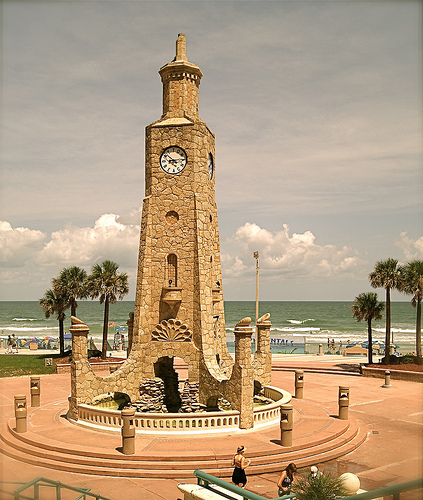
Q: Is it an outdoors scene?
A: Yes, it is outdoors.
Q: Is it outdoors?
A: Yes, it is outdoors.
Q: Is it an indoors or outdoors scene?
A: It is outdoors.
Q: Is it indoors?
A: No, it is outdoors.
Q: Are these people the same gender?
A: Yes, all the people are female.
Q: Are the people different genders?
A: No, all the people are female.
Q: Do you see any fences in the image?
A: No, there are no fences.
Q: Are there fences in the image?
A: No, there are no fences.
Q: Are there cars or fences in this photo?
A: No, there are no fences or cars.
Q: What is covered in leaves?
A: The palm is covered in leaves.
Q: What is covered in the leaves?
A: The palm is covered in leaves.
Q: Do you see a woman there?
A: Yes, there is a woman.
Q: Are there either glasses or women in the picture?
A: Yes, there is a woman.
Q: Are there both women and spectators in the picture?
A: No, there is a woman but no spectators.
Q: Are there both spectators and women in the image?
A: No, there is a woman but no spectators.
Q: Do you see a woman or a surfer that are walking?
A: Yes, the woman is walking.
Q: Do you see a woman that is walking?
A: Yes, there is a woman that is walking.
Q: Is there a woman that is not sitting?
A: Yes, there is a woman that is walking.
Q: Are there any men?
A: No, there are no men.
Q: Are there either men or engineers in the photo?
A: No, there are no men or engineers.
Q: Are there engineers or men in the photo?
A: No, there are no men or engineers.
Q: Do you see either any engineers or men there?
A: No, there are no men or engineers.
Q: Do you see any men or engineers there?
A: No, there are no men or engineers.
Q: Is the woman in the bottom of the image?
A: Yes, the woman is in the bottom of the image.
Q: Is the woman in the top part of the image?
A: No, the woman is in the bottom of the image.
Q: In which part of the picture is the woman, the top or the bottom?
A: The woman is in the bottom of the image.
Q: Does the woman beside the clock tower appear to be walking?
A: Yes, the woman is walking.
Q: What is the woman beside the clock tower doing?
A: The woman is walking.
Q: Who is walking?
A: The woman is walking.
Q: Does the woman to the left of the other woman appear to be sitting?
A: No, the woman is walking.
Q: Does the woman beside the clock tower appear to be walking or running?
A: The woman is walking.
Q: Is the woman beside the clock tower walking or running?
A: The woman is walking.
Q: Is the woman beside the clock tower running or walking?
A: The woman is walking.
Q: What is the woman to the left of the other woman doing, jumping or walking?
A: The woman is walking.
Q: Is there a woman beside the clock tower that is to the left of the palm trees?
A: Yes, there is a woman beside the clock tower.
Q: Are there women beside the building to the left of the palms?
A: Yes, there is a woman beside the clock tower.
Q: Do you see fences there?
A: No, there are no fences.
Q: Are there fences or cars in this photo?
A: No, there are no fences or cars.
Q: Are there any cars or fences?
A: No, there are no fences or cars.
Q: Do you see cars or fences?
A: No, there are no fences or cars.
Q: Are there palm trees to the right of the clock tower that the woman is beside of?
A: Yes, there are palm trees to the right of the clock tower.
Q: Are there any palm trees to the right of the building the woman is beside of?
A: Yes, there are palm trees to the right of the clock tower.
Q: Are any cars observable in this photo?
A: No, there are no cars.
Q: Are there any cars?
A: No, there are no cars.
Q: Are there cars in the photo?
A: No, there are no cars.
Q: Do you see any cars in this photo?
A: No, there are no cars.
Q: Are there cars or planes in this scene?
A: No, there are no cars or planes.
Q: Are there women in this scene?
A: Yes, there is a woman.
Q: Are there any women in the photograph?
A: Yes, there is a woman.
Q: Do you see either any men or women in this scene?
A: Yes, there is a woman.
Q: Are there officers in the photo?
A: No, there are no officers.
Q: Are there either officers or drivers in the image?
A: No, there are no officers or drivers.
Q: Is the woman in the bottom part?
A: Yes, the woman is in the bottom of the image.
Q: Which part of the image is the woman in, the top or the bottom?
A: The woman is in the bottom of the image.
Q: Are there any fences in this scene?
A: No, there are no fences.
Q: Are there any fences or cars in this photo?
A: No, there are no fences or cars.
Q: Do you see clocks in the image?
A: Yes, there is a clock.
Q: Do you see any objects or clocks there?
A: Yes, there is a clock.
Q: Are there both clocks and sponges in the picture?
A: No, there is a clock but no sponges.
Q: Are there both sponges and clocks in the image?
A: No, there is a clock but no sponges.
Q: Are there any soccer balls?
A: No, there are no soccer balls.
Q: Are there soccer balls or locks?
A: No, there are no soccer balls or locks.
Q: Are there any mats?
A: No, there are no mats.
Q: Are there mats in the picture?
A: No, there are no mats.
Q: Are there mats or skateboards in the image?
A: No, there are no mats or skateboards.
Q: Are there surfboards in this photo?
A: No, there are no surfboards.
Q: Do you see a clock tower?
A: Yes, there is a clock tower.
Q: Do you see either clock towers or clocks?
A: Yes, there is a clock tower.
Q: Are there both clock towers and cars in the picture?
A: No, there is a clock tower but no cars.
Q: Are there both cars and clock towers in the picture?
A: No, there is a clock tower but no cars.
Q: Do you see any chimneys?
A: No, there are no chimneys.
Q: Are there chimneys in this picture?
A: No, there are no chimneys.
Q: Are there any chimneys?
A: No, there are no chimneys.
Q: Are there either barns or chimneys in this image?
A: No, there are no chimneys or barns.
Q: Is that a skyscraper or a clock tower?
A: That is a clock tower.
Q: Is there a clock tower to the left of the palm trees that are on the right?
A: Yes, there is a clock tower to the left of the palms.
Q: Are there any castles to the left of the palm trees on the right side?
A: No, there is a clock tower to the left of the palm trees.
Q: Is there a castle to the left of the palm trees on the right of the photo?
A: No, there is a clock tower to the left of the palm trees.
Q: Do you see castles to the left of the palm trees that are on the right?
A: No, there is a clock tower to the left of the palm trees.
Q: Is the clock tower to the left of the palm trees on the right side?
A: Yes, the clock tower is to the left of the palms.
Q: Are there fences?
A: No, there are no fences.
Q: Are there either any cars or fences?
A: No, there are no fences or cars.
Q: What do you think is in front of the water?
A: The trees are in front of the water.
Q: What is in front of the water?
A: The trees are in front of the water.